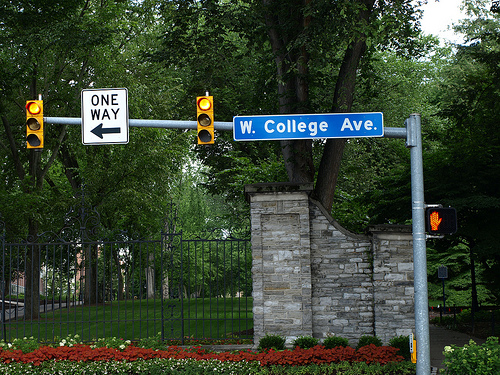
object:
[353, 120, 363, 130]
letter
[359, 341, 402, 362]
tree stump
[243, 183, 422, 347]
wall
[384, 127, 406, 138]
pole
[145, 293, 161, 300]
stump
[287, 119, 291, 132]
letter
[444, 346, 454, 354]
flower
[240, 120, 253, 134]
letter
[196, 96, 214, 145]
light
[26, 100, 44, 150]
light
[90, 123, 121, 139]
arrow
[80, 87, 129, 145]
sign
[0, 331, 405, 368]
flowers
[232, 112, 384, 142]
sign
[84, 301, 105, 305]
stump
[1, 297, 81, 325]
street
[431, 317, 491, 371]
street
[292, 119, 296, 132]
letter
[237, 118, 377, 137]
lettering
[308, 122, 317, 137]
letter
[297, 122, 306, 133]
letter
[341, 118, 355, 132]
letter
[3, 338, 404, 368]
red flowers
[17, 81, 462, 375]
light post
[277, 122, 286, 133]
letter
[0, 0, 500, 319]
tree